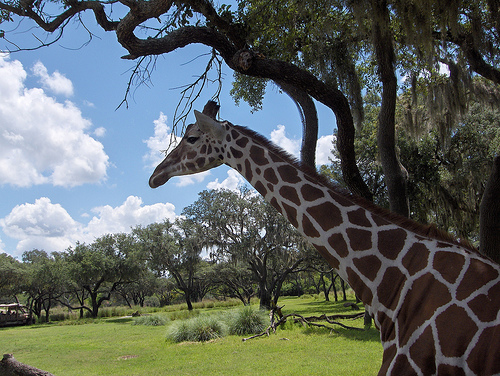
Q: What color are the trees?
A: Green.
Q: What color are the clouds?
A: White.